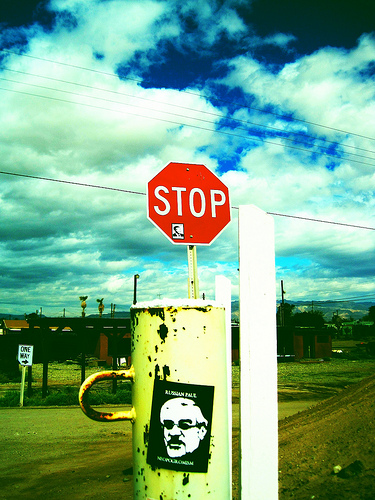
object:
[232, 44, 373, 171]
cloud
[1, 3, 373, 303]
sky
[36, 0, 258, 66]
cloud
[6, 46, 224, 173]
cloud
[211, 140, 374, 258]
cloud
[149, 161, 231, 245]
sign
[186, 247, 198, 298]
pole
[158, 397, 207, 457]
man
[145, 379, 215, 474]
poster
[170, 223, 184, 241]
sticker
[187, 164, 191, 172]
screw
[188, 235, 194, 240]
screw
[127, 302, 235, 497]
post